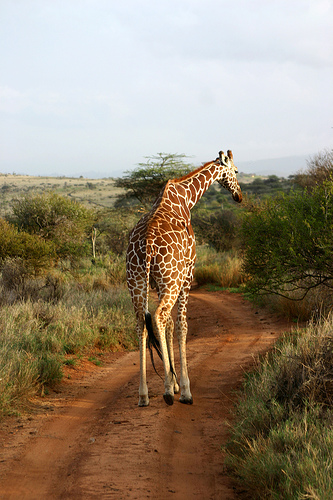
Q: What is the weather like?
A: It is cloudy.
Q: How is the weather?
A: It is cloudy.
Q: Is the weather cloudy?
A: Yes, it is cloudy.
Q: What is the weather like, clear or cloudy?
A: It is cloudy.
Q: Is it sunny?
A: No, it is cloudy.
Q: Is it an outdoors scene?
A: Yes, it is outdoors.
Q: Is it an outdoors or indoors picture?
A: It is outdoors.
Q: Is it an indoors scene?
A: No, it is outdoors.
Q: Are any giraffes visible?
A: Yes, there is a giraffe.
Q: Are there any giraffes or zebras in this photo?
A: Yes, there is a giraffe.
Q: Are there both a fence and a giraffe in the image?
A: No, there is a giraffe but no fences.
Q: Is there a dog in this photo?
A: No, there are no dogs.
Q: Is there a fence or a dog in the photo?
A: No, there are no dogs or fences.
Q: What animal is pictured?
A: The animal is a giraffe.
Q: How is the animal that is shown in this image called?
A: The animal is a giraffe.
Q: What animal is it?
A: The animal is a giraffe.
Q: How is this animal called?
A: This is a giraffe.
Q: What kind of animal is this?
A: This is a giraffe.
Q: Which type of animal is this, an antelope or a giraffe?
A: This is a giraffe.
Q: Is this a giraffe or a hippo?
A: This is a giraffe.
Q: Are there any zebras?
A: No, there are no zebras.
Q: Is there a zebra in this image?
A: No, there are no zebras.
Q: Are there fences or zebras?
A: No, there are no zebras or fences.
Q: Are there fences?
A: No, there are no fences.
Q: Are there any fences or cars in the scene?
A: No, there are no fences or cars.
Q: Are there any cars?
A: No, there are no cars.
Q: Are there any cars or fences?
A: No, there are no cars or fences.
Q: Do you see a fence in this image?
A: No, there are no fences.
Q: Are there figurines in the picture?
A: No, there are no figurines.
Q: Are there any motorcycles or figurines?
A: No, there are no figurines or motorcycles.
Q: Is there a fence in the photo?
A: No, there are no fences.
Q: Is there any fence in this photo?
A: No, there are no fences.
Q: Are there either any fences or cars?
A: No, there are no fences or cars.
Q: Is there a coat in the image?
A: Yes, there is a coat.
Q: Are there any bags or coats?
A: Yes, there is a coat.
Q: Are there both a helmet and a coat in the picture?
A: No, there is a coat but no helmets.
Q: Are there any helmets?
A: No, there are no helmets.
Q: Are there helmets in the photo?
A: No, there are no helmets.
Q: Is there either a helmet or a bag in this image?
A: No, there are no helmets or bags.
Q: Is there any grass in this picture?
A: Yes, there is grass.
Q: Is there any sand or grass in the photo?
A: Yes, there is grass.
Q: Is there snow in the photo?
A: No, there is no snow.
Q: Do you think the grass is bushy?
A: Yes, the grass is bushy.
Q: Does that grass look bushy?
A: Yes, the grass is bushy.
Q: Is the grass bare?
A: No, the grass is bushy.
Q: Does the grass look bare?
A: No, the grass is bushy.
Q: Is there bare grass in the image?
A: No, there is grass but it is bushy.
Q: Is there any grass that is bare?
A: No, there is grass but it is bushy.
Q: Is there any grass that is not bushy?
A: No, there is grass but it is bushy.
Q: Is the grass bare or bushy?
A: The grass is bushy.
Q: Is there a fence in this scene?
A: No, there are no fences.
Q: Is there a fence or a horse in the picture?
A: No, there are no fences or horses.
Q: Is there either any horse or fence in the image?
A: No, there are no fences or horses.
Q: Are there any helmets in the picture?
A: No, there are no helmets.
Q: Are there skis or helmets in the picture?
A: No, there are no helmets or skis.